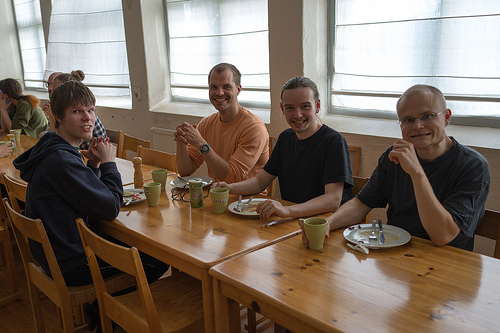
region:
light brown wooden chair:
[68, 215, 223, 331]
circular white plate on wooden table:
[340, 219, 415, 251]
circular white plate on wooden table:
[226, 192, 287, 219]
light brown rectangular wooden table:
[201, 208, 498, 332]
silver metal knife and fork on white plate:
[366, 214, 388, 247]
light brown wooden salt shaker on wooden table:
[130, 152, 146, 190]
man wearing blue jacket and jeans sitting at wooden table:
[10, 78, 171, 331]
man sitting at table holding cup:
[293, 81, 495, 285]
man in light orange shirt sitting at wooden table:
[159, 60, 271, 235]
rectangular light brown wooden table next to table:
[71, 168, 348, 332]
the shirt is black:
[355, 143, 492, 235]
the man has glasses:
[360, 85, 485, 253]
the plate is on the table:
[345, 218, 404, 260]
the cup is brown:
[291, 220, 332, 253]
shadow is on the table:
[400, 264, 472, 331]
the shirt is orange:
[204, 119, 264, 176]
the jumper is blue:
[19, 148, 127, 263]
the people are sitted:
[197, 69, 470, 244]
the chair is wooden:
[82, 220, 160, 318]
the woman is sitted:
[54, 69, 108, 140]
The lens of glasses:
[405, 117, 414, 122]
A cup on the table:
[312, 229, 322, 246]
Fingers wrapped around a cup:
[304, 236, 306, 246]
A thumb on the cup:
[325, 234, 327, 239]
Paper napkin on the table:
[358, 247, 365, 249]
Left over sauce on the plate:
[365, 231, 369, 233]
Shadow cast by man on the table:
[418, 283, 437, 301]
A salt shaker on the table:
[136, 166, 141, 185]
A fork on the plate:
[372, 233, 374, 238]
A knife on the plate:
[380, 235, 383, 243]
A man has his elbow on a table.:
[385, 135, 464, 249]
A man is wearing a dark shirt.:
[357, 130, 493, 254]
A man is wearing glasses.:
[397, 106, 449, 128]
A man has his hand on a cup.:
[293, 193, 368, 253]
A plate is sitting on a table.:
[338, 219, 413, 251]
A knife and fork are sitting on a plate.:
[360, 217, 388, 252]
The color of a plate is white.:
[342, 220, 416, 252]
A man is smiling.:
[203, 63, 246, 117]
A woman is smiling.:
[275, 78, 322, 138]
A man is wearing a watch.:
[192, 139, 214, 156]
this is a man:
[321, 76, 491, 257]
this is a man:
[269, 53, 356, 233]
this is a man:
[178, 55, 274, 226]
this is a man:
[12, 70, 134, 280]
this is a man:
[15, 68, 127, 181]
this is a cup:
[292, 206, 339, 271]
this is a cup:
[200, 160, 245, 230]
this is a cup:
[190, 177, 204, 214]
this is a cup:
[136, 172, 167, 223]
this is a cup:
[141, 156, 171, 196]